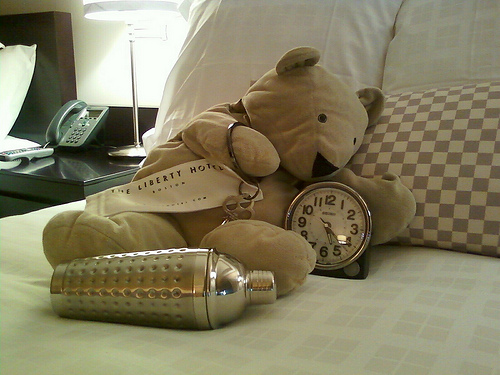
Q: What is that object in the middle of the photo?
A: A teddy bear.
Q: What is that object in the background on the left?
A: A telephone.